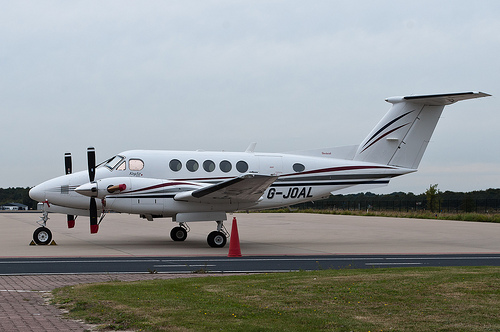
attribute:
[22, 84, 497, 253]
plane — on runway, beechcraft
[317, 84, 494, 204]
tail — vertical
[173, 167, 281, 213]
wing — horizontal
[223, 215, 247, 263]
cone — on ground, orange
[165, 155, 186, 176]
window — round, small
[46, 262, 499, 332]
grass — green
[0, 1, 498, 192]
sky — blue, cloudy, gray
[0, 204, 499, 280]
runway — paved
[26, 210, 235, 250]
landing gear — for takeoff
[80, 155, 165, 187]
cockpit — for pilot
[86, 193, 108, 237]
propeller — red, black